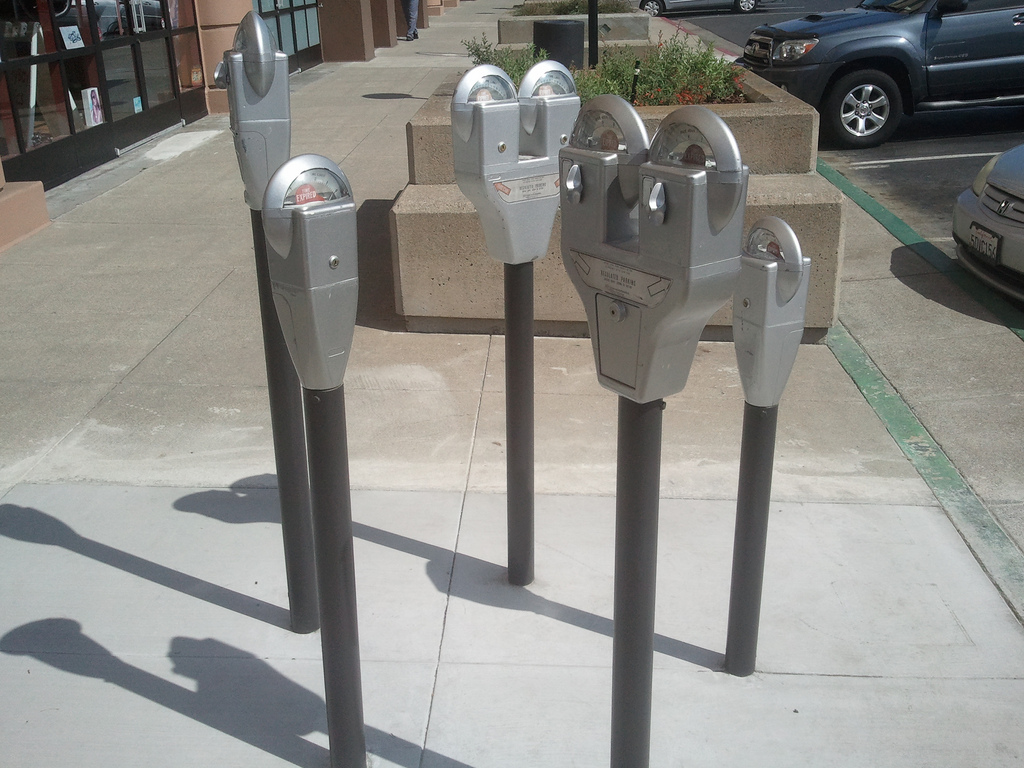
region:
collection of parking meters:
[166, 41, 824, 675]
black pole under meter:
[617, 389, 693, 760]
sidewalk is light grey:
[857, 538, 1020, 707]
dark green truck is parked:
[746, 3, 1021, 137]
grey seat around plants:
[406, 32, 856, 362]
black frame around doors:
[29, 0, 210, 178]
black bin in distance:
[526, 26, 587, 69]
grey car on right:
[924, 126, 1020, 278]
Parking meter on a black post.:
[262, 150, 373, 765]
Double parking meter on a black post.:
[564, 90, 749, 764]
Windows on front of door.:
[14, 0, 179, 204]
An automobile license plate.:
[961, 223, 999, 266]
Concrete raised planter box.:
[398, 63, 848, 330]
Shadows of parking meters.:
[0, 466, 263, 765]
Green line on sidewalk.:
[826, 321, 1017, 636]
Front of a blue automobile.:
[746, 5, 1021, 148]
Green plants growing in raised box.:
[446, 28, 734, 115]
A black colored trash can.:
[526, 18, 588, 77]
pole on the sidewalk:
[735, 591, 781, 664]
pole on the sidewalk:
[621, 670, 664, 750]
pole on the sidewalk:
[504, 524, 549, 598]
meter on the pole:
[724, 220, 816, 402]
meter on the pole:
[457, 72, 578, 265]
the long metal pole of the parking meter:
[299, 379, 383, 763]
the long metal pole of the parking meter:
[602, 392, 669, 766]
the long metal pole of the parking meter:
[716, 398, 786, 668]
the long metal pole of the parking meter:
[500, 251, 546, 585]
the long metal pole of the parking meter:
[245, 202, 334, 635]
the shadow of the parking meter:
[4, 608, 331, 765]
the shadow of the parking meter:
[2, 497, 293, 641]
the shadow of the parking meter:
[424, 553, 728, 674]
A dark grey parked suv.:
[736, 2, 1022, 146]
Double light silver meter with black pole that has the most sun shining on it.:
[455, 63, 583, 582]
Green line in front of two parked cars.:
[817, 158, 1023, 345]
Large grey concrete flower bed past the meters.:
[387, 47, 843, 345]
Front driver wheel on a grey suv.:
[820, 69, 906, 146]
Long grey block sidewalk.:
[2, 0, 522, 506]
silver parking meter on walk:
[255, 136, 376, 766]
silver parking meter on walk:
[552, 83, 756, 764]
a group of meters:
[192, 22, 861, 735]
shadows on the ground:
[12, 420, 367, 747]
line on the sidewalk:
[841, 304, 1010, 615]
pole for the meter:
[587, 376, 689, 762]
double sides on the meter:
[537, 47, 771, 428]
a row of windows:
[12, 19, 194, 146]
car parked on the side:
[755, 18, 1013, 162]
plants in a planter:
[475, 22, 752, 122]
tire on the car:
[825, 59, 901, 154]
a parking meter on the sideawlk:
[737, 218, 848, 572]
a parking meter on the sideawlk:
[204, 162, 397, 644]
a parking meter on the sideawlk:
[157, 45, 379, 381]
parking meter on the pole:
[614, 186, 695, 578]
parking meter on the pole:
[734, 148, 774, 627]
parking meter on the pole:
[204, 54, 306, 220]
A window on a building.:
[100, 43, 143, 116]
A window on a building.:
[139, 36, 178, 100]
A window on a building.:
[62, 54, 110, 121]